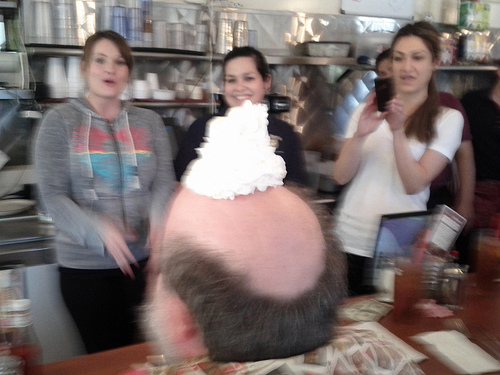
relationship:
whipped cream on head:
[180, 100, 288, 201] [135, 175, 342, 360]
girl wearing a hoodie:
[31, 30, 180, 351] [31, 96, 177, 273]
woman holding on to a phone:
[330, 20, 467, 293] [372, 77, 398, 115]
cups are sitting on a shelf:
[43, 54, 87, 100] [32, 89, 222, 111]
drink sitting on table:
[392, 255, 424, 322] [19, 270, 499, 374]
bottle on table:
[8, 298, 44, 373] [19, 270, 499, 374]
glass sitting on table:
[394, 257, 423, 321] [19, 270, 499, 374]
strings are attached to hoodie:
[84, 113, 139, 178] [31, 96, 177, 273]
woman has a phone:
[330, 20, 467, 293] [372, 77, 398, 115]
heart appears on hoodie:
[71, 122, 153, 196] [31, 96, 177, 273]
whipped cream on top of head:
[180, 100, 288, 201] [135, 175, 342, 360]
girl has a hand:
[330, 21, 467, 299] [384, 99, 410, 131]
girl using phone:
[330, 21, 467, 299] [372, 77, 398, 115]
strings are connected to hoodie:
[84, 113, 139, 178] [31, 96, 177, 273]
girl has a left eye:
[31, 30, 180, 351] [115, 57, 125, 68]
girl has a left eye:
[330, 21, 467, 299] [412, 54, 424, 62]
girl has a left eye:
[172, 46, 312, 193] [244, 75, 254, 84]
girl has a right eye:
[31, 30, 180, 351] [96, 56, 104, 64]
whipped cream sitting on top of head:
[180, 100, 288, 201] [135, 175, 342, 360]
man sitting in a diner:
[129, 177, 428, 375] [3, 1, 498, 374]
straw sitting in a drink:
[415, 229, 432, 268] [392, 255, 424, 322]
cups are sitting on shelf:
[43, 54, 87, 100] [32, 89, 222, 111]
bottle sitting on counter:
[8, 298, 44, 373] [3, 267, 499, 375]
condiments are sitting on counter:
[3, 295, 47, 374] [3, 267, 499, 375]